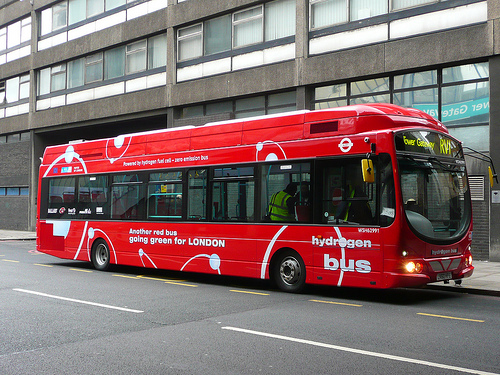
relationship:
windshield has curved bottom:
[395, 127, 472, 240] [408, 229, 477, 239]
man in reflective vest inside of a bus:
[255, 165, 289, 240] [59, 170, 435, 282]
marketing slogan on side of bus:
[117, 229, 230, 243] [32, 108, 476, 375]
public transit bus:
[178, 150, 254, 297] [33, 115, 413, 199]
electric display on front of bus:
[392, 128, 463, 159] [34, 103, 474, 293]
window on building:
[0, 79, 7, 105] [0, 1, 498, 261]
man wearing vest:
[266, 182, 299, 223] [267, 188, 293, 221]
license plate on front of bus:
[433, 268, 453, 285] [34, 103, 474, 293]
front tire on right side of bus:
[272, 251, 305, 293] [34, 103, 474, 293]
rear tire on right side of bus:
[88, 239, 110, 269] [34, 103, 474, 293]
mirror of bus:
[361, 159, 374, 182] [34, 103, 474, 293]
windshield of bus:
[395, 150, 471, 242] [34, 103, 474, 293]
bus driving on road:
[34, 103, 474, 293] [2, 240, 498, 371]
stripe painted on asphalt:
[217, 323, 497, 370] [0, 239, 500, 372]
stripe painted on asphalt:
[11, 286, 144, 315] [0, 239, 500, 372]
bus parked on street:
[34, 103, 474, 293] [0, 239, 498, 373]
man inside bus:
[266, 182, 299, 223] [34, 103, 474, 293]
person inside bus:
[333, 181, 373, 226] [34, 103, 474, 293]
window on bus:
[106, 173, 143, 218] [34, 103, 474, 293]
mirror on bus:
[359, 158, 379, 184] [34, 103, 474, 293]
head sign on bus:
[395, 129, 464, 160] [34, 103, 474, 293]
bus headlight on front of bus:
[405, 260, 423, 274] [34, 103, 474, 293]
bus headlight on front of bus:
[465, 255, 473, 265] [34, 103, 474, 293]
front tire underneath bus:
[271, 248, 306, 293] [34, 103, 474, 293]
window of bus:
[47, 175, 77, 220] [34, 103, 474, 293]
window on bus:
[47, 175, 77, 220] [28, 92, 483, 288]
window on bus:
[77, 177, 107, 213] [34, 103, 474, 293]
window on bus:
[106, 169, 146, 221] [34, 103, 474, 293]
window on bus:
[147, 168, 184, 222] [34, 103, 474, 293]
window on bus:
[186, 168, 205, 221] [34, 103, 474, 293]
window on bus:
[215, 167, 254, 224] [34, 103, 474, 293]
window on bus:
[326, 153, 393, 233] [34, 103, 474, 293]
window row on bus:
[42, 150, 393, 226] [34, 103, 474, 293]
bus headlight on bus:
[405, 260, 423, 274] [34, 103, 474, 293]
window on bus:
[39, 172, 77, 218] [34, 103, 474, 293]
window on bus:
[77, 174, 109, 221] [34, 103, 474, 293]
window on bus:
[211, 163, 254, 218] [34, 103, 474, 293]